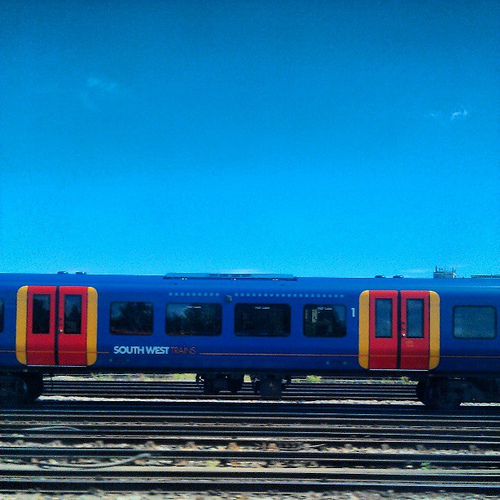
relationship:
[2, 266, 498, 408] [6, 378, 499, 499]
train on tracks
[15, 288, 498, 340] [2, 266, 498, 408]
windows on train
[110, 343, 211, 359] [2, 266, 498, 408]
writing on train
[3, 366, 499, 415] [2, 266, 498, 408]
wheels on train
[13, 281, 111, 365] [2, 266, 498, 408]
doors on train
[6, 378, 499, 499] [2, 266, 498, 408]
tracks besides train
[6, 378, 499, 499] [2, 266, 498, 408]
tracks underneath train